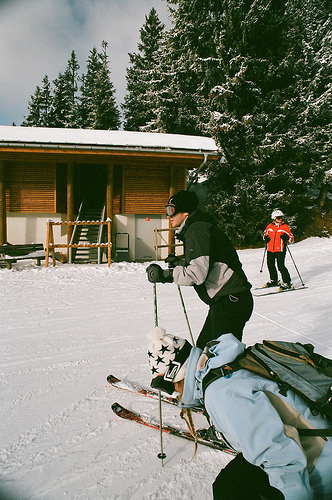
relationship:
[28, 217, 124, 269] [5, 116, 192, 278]
bench beside house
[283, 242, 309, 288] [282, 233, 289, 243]
pole in hand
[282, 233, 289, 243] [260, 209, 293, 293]
hand of skier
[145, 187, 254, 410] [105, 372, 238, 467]
man standing on skiis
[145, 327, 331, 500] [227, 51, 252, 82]
skier wearing blue jacket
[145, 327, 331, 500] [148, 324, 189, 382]
skier wearing hat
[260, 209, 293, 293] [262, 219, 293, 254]
skier wearing red coat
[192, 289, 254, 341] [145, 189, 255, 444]
pants on a man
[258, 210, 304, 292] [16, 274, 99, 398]
skier in snow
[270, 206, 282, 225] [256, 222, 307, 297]
helmet on skier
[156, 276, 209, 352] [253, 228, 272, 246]
pole in hand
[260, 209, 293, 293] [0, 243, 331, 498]
skier in snow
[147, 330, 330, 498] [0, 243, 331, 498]
skier in snow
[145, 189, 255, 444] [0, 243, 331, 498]
man in snow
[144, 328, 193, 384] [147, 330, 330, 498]
hat on skier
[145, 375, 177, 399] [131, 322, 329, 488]
goggles on skier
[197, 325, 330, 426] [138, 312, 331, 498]
backpack on skier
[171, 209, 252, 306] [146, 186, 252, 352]
jacket on man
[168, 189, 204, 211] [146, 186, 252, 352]
black hat on man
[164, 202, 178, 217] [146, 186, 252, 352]
goggles on man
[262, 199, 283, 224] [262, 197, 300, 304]
helmet on woman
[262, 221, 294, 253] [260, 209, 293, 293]
red coat on skier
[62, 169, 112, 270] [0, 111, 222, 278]
stairs on house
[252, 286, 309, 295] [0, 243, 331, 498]
ski on snow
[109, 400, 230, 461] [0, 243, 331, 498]
ski on snow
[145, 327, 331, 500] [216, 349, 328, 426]
skier has back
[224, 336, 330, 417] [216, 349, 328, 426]
backpack in back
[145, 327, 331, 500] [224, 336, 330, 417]
skier wearing backpack